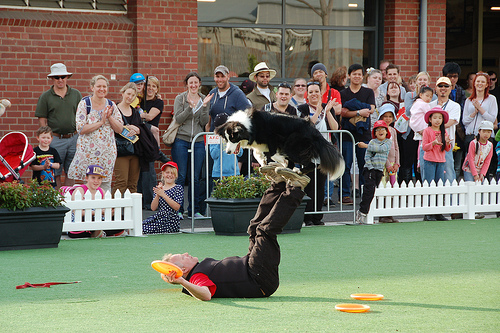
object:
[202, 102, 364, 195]
dog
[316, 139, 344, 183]
tail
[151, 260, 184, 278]
frisbee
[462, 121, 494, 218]
girl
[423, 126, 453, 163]
tshirt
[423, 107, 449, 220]
girl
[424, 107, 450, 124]
hat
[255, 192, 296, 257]
leg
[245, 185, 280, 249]
leg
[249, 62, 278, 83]
hat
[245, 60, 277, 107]
guy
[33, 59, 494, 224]
viewers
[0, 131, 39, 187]
stroller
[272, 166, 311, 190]
shoes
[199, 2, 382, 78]
window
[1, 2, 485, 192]
building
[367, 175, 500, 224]
fence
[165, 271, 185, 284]
hand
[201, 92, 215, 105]
hand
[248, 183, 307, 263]
pants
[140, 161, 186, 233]
girl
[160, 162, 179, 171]
hat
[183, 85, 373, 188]
canine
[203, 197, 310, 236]
pot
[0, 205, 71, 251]
pot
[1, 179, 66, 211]
plant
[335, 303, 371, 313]
frisbee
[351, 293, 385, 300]
frisbee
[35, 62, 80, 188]
man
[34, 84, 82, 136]
shirt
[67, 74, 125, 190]
woman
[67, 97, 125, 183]
dress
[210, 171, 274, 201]
plant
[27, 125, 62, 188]
boy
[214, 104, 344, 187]
dog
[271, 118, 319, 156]
black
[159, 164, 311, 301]
entertainer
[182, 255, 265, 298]
vest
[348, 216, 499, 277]
lawn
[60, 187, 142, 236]
fence